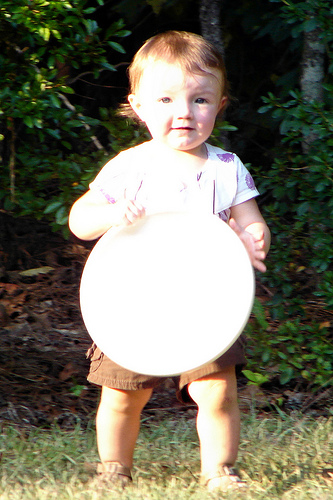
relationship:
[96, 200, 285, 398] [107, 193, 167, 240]
frisbee in hand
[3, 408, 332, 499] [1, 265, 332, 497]
grass on ground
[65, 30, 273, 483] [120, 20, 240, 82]
baby has hair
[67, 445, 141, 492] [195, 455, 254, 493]
sandal on foot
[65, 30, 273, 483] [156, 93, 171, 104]
baby has eye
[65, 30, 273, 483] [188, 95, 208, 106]
baby has eye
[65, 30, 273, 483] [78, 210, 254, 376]
baby has frisbee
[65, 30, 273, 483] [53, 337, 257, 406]
baby wears shorts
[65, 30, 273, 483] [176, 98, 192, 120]
baby has nose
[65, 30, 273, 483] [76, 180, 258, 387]
baby has frisbee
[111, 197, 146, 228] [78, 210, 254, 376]
hand holds frisbee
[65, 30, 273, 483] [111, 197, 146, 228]
baby has hand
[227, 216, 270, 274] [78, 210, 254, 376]
hand grips frisbee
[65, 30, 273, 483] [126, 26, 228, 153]
baby has head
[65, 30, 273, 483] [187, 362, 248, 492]
baby has leg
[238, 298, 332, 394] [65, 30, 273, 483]
leaves behind baby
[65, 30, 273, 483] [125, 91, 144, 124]
baby has ear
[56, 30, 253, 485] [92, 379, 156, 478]
baby has leg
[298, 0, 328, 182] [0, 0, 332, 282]
tree in woods